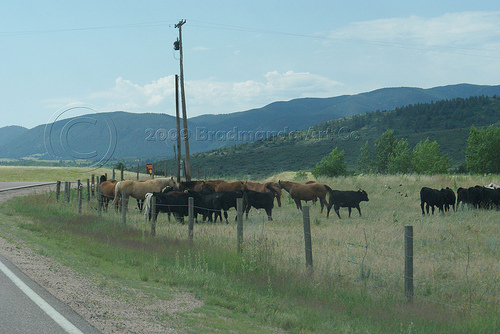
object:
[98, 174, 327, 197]
horse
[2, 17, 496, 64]
wire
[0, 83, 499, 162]
mountains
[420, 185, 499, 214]
cows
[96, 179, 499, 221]
livestock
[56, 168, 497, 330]
fence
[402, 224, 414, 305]
pole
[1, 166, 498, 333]
pasture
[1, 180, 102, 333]
road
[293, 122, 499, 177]
trees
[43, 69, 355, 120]
cloud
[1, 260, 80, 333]
mark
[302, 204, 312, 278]
wood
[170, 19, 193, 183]
post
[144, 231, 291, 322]
plants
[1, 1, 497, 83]
sky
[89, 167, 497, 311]
pasture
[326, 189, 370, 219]
cow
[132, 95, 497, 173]
trees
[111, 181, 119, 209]
tail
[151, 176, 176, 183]
mane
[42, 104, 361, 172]
copyright